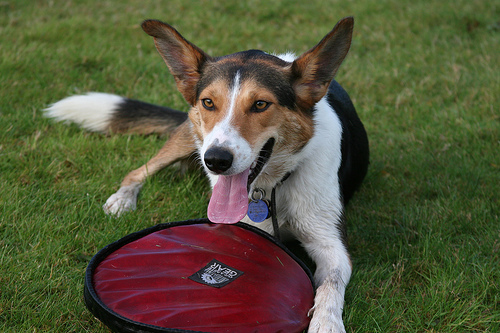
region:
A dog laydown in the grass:
[28, 19, 390, 321]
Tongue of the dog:
[206, 182, 258, 232]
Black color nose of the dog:
[198, 145, 245, 182]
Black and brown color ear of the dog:
[141, 18, 373, 78]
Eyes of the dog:
[201, 92, 286, 114]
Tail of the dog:
[46, 78, 160, 138]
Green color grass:
[400, 44, 465, 222]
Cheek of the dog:
[241, 120, 266, 148]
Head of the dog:
[136, 15, 348, 230]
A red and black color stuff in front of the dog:
[76, 240, 307, 331]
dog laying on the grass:
[30, 14, 389, 331]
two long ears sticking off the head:
[137, 5, 370, 113]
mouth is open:
[192, 130, 274, 228]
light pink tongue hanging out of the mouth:
[194, 151, 259, 230]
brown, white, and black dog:
[43, 13, 415, 332]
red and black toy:
[62, 201, 314, 331]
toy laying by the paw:
[64, 210, 356, 330]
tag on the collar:
[242, 187, 274, 224]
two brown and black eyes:
[191, 92, 278, 112]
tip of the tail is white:
[32, 78, 117, 135]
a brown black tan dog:
[69, 16, 435, 228]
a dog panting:
[47, 5, 387, 236]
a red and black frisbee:
[58, 222, 336, 331]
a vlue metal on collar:
[236, 196, 273, 226]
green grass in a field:
[370, 165, 482, 316]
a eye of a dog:
[246, 94, 281, 119]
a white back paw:
[94, 189, 141, 226]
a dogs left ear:
[291, 15, 372, 110]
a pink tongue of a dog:
[194, 177, 261, 222]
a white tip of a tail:
[38, 77, 115, 141]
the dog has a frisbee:
[53, 175, 348, 327]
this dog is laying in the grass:
[40, 12, 418, 235]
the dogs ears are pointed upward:
[123, 10, 379, 93]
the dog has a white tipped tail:
[43, 73, 173, 140]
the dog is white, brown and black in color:
[69, 15, 390, 230]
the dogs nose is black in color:
[188, 133, 244, 183]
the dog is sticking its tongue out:
[188, 163, 265, 238]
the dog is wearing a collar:
[248, 185, 297, 241]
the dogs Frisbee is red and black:
[81, 205, 329, 322]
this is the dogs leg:
[312, 206, 357, 331]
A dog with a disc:
[21, 16, 403, 328]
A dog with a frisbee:
[20, 10, 385, 320]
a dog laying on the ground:
[15, 5, 425, 330]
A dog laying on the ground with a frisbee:
[15, 6, 410, 327]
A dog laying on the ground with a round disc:
[14, 15, 426, 332]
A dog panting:
[37, 9, 390, 259]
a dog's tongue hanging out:
[200, 133, 260, 229]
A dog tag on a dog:
[242, 186, 272, 224]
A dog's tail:
[35, 80, 183, 140]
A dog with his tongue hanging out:
[11, 13, 394, 230]